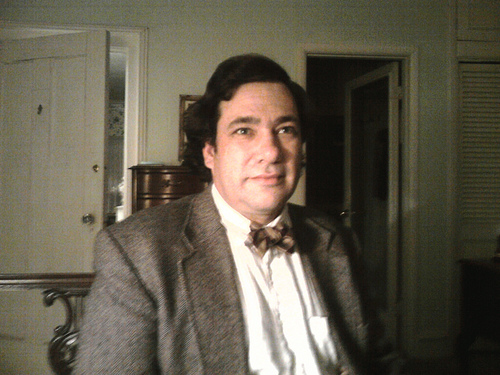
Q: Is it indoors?
A: Yes, it is indoors.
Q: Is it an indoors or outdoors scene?
A: It is indoors.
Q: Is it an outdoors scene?
A: No, it is indoors.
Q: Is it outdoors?
A: No, it is indoors.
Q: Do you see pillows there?
A: No, there are no pillows.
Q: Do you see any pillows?
A: No, there are no pillows.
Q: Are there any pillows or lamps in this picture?
A: No, there are no pillows or lamps.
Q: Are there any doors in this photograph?
A: Yes, there is a door.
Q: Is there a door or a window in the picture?
A: Yes, there is a door.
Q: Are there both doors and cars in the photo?
A: No, there is a door but no cars.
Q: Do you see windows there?
A: No, there are no windows.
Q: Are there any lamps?
A: No, there are no lamps.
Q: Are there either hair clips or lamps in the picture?
A: No, there are no lamps or hair clips.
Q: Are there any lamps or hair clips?
A: No, there are no lamps or hair clips.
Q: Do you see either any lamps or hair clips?
A: No, there are no lamps or hair clips.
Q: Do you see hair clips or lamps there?
A: No, there are no lamps or hair clips.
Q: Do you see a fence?
A: No, there are no fences.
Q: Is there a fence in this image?
A: No, there are no fences.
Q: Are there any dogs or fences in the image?
A: No, there are no fences or dogs.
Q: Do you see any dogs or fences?
A: No, there are no fences or dogs.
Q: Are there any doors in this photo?
A: Yes, there is a door.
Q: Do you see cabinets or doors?
A: Yes, there is a door.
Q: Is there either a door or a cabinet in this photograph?
A: Yes, there is a door.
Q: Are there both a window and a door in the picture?
A: No, there is a door but no windows.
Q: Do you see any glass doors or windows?
A: Yes, there is a glass door.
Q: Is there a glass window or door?
A: Yes, there is a glass door.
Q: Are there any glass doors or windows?
A: Yes, there is a glass door.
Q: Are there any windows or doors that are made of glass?
A: Yes, the door is made of glass.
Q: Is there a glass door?
A: Yes, there is a door that is made of glass.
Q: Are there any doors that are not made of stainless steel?
A: Yes, there is a door that is made of glass.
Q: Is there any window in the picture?
A: No, there are no windows.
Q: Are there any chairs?
A: Yes, there is a chair.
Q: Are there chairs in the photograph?
A: Yes, there is a chair.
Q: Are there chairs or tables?
A: Yes, there is a chair.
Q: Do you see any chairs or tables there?
A: Yes, there is a chair.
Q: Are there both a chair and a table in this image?
A: No, there is a chair but no tables.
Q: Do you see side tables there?
A: No, there are no side tables.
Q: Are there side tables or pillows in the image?
A: No, there are no side tables or pillows.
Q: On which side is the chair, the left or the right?
A: The chair is on the left of the image.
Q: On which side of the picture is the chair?
A: The chair is on the left of the image.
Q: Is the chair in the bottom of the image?
A: Yes, the chair is in the bottom of the image.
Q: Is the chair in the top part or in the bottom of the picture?
A: The chair is in the bottom of the image.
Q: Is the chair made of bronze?
A: Yes, the chair is made of bronze.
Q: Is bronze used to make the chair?
A: Yes, the chair is made of bronze.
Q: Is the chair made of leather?
A: No, the chair is made of bronze.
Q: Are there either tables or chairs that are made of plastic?
A: No, there is a chair but it is made of bronze.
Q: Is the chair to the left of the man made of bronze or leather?
A: The chair is made of bronze.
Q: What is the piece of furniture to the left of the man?
A: The piece of furniture is a chair.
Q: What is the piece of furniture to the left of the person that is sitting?
A: The piece of furniture is a chair.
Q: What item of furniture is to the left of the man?
A: The piece of furniture is a chair.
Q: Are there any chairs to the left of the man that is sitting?
A: Yes, there is a chair to the left of the man.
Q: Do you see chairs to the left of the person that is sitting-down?
A: Yes, there is a chair to the left of the man.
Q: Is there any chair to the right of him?
A: No, the chair is to the left of the man.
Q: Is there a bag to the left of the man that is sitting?
A: No, there is a chair to the left of the man.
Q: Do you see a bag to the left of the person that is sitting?
A: No, there is a chair to the left of the man.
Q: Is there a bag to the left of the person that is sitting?
A: No, there is a chair to the left of the man.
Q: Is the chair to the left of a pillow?
A: No, the chair is to the left of a man.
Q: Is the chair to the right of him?
A: No, the chair is to the left of the man.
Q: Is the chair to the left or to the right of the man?
A: The chair is to the left of the man.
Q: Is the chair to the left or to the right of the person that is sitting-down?
A: The chair is to the left of the man.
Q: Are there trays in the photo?
A: No, there are no trays.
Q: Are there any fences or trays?
A: No, there are no trays or fences.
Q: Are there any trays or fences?
A: No, there are no trays or fences.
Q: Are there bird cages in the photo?
A: No, there are no bird cages.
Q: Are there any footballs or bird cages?
A: No, there are no bird cages or footballs.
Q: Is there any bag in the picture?
A: No, there are no bags.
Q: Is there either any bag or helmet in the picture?
A: No, there are no bags or helmets.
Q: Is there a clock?
A: No, there are no clocks.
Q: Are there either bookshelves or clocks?
A: No, there are no clocks or bookshelves.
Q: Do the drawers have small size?
A: Yes, the drawers are small.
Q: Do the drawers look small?
A: Yes, the drawers are small.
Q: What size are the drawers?
A: The drawers are small.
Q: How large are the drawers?
A: The drawers are small.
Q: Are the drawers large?
A: No, the drawers are small.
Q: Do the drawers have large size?
A: No, the drawers are small.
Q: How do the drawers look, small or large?
A: The drawers are small.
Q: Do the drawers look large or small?
A: The drawers are small.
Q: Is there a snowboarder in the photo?
A: No, there are no snowboarders.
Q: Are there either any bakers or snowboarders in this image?
A: No, there are no snowboarders or bakers.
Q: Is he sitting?
A: Yes, the man is sitting.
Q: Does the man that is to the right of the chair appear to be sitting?
A: Yes, the man is sitting.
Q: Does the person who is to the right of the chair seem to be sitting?
A: Yes, the man is sitting.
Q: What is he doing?
A: The man is sitting.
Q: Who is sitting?
A: The man is sitting.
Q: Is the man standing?
A: No, the man is sitting.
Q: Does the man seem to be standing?
A: No, the man is sitting.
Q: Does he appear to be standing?
A: No, the man is sitting.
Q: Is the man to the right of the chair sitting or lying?
A: The man is sitting.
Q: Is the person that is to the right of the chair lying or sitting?
A: The man is sitting.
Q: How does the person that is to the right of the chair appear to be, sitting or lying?
A: The man is sitting.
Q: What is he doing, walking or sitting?
A: The man is sitting.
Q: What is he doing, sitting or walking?
A: The man is sitting.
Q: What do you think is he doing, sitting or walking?
A: The man is sitting.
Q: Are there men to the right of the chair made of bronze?
A: Yes, there is a man to the right of the chair.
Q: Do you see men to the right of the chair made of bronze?
A: Yes, there is a man to the right of the chair.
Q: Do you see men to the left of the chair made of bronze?
A: No, the man is to the right of the chair.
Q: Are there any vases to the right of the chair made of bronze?
A: No, there is a man to the right of the chair.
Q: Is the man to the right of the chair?
A: Yes, the man is to the right of the chair.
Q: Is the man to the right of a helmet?
A: No, the man is to the right of the chair.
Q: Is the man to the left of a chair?
A: No, the man is to the right of a chair.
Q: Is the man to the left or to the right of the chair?
A: The man is to the right of the chair.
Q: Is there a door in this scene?
A: Yes, there is a door.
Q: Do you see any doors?
A: Yes, there is a door.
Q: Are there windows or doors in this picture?
A: Yes, there is a door.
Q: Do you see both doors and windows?
A: No, there is a door but no windows.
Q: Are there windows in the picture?
A: No, there are no windows.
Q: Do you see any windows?
A: No, there are no windows.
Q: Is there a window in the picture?
A: No, there are no windows.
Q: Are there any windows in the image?
A: No, there are no windows.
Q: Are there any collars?
A: Yes, there is a collar.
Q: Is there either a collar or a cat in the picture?
A: Yes, there is a collar.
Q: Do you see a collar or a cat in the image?
A: Yes, there is a collar.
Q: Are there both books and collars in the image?
A: No, there is a collar but no books.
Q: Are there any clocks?
A: No, there are no clocks.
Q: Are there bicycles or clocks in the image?
A: No, there are no clocks or bicycles.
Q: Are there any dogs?
A: No, there are no dogs.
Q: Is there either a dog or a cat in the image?
A: No, there are no dogs or cats.